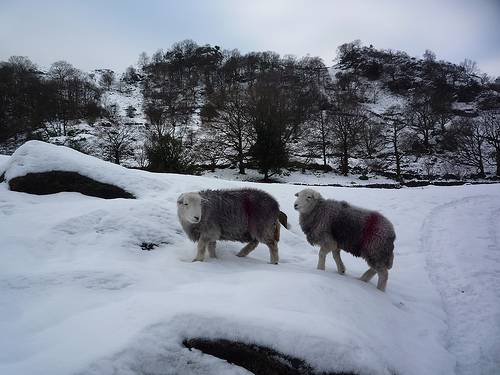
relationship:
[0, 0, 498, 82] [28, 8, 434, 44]
clouds in sky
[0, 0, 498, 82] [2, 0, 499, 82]
clouds in sky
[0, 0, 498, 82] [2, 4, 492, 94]
clouds in sky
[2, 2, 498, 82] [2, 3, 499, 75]
clouds in sky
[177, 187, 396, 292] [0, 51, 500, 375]
sheep climbs snow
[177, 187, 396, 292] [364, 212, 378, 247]
sheep has marker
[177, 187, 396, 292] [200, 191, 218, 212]
sheep looks over shoulder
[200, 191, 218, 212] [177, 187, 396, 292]
shoulder of sheep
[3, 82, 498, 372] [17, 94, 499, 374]
snow covers hillside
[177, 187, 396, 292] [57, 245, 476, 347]
sheep on snow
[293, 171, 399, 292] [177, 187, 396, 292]
sheep following sheep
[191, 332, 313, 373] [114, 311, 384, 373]
wedge between snow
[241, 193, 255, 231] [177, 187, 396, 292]
spot over sheep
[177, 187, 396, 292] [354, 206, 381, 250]
sheep with stripe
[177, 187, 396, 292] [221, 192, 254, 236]
sheep with stripe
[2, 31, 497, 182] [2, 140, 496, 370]
trees on mountain top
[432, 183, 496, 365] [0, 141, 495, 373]
tracks in snow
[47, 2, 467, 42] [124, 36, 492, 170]
sky behind trees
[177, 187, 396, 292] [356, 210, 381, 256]
sheep with spot